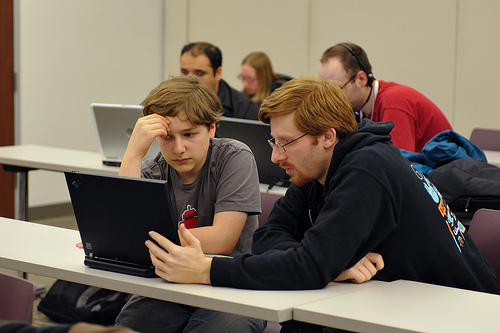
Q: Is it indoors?
A: Yes, it is indoors.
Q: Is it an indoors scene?
A: Yes, it is indoors.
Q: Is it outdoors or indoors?
A: It is indoors.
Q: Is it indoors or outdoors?
A: It is indoors.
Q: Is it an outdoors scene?
A: No, it is indoors.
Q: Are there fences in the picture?
A: No, there are no fences.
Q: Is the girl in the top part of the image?
A: Yes, the girl is in the top of the image.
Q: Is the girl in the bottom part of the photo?
A: No, the girl is in the top of the image.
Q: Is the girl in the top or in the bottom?
A: The girl is in the top of the image.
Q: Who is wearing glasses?
A: The girl is wearing glasses.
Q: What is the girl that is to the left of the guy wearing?
A: The girl is wearing glasses.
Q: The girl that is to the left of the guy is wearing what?
A: The girl is wearing glasses.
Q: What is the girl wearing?
A: The girl is wearing glasses.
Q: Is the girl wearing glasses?
A: Yes, the girl is wearing glasses.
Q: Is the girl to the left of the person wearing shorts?
A: No, the girl is wearing glasses.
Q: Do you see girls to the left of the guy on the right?
A: Yes, there is a girl to the left of the guy.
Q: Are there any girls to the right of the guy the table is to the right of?
A: No, the girl is to the left of the guy.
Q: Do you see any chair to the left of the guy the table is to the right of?
A: No, there is a girl to the left of the guy.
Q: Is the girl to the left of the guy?
A: Yes, the girl is to the left of the guy.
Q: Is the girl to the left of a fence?
A: No, the girl is to the left of the guy.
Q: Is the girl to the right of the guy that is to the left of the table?
A: No, the girl is to the left of the guy.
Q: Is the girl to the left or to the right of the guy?
A: The girl is to the left of the guy.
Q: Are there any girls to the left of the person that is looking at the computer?
A: Yes, there is a girl to the left of the person.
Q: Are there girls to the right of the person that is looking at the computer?
A: No, the girl is to the left of the person.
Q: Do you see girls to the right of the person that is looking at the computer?
A: No, the girl is to the left of the person.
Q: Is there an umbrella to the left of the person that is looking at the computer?
A: No, there is a girl to the left of the person.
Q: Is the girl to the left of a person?
A: Yes, the girl is to the left of a person.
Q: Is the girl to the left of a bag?
A: No, the girl is to the left of a person.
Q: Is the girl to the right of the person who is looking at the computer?
A: No, the girl is to the left of the person.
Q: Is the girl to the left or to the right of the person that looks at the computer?
A: The girl is to the left of the person.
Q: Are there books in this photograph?
A: No, there are no books.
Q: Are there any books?
A: No, there are no books.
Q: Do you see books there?
A: No, there are no books.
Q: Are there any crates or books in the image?
A: No, there are no books or crates.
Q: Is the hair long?
A: Yes, the hair is long.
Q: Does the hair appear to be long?
A: Yes, the hair is long.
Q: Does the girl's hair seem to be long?
A: Yes, the hair is long.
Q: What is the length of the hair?
A: The hair is long.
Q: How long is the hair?
A: The hair is long.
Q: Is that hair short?
A: No, the hair is long.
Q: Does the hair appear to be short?
A: No, the hair is long.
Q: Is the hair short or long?
A: The hair is long.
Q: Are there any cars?
A: No, there are no cars.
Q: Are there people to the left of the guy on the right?
A: Yes, there is a person to the left of the guy.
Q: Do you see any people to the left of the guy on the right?
A: Yes, there is a person to the left of the guy.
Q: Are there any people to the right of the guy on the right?
A: No, the person is to the left of the guy.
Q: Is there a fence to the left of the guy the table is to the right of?
A: No, there is a person to the left of the guy.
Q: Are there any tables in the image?
A: Yes, there is a table.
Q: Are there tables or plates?
A: Yes, there is a table.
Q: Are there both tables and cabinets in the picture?
A: No, there is a table but no cabinets.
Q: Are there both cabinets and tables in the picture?
A: No, there is a table but no cabinets.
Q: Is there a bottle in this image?
A: No, there are no bottles.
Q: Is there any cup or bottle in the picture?
A: No, there are no bottles or cups.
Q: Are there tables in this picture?
A: Yes, there is a table.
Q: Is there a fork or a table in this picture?
A: Yes, there is a table.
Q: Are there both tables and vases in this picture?
A: No, there is a table but no vases.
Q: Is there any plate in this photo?
A: No, there are no plates.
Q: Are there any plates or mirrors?
A: No, there are no plates or mirrors.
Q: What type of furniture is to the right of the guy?
A: The piece of furniture is a table.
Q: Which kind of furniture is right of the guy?
A: The piece of furniture is a table.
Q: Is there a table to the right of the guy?
A: Yes, there is a table to the right of the guy.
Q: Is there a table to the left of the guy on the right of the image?
A: No, the table is to the right of the guy.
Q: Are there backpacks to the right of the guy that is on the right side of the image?
A: No, there is a table to the right of the guy.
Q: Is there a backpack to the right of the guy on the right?
A: No, there is a table to the right of the guy.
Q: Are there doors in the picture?
A: Yes, there is a door.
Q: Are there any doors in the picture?
A: Yes, there is a door.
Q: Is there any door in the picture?
A: Yes, there is a door.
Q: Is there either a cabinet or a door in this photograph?
A: Yes, there is a door.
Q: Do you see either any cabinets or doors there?
A: Yes, there is a door.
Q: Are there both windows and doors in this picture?
A: No, there is a door but no windows.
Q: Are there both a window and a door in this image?
A: No, there is a door but no windows.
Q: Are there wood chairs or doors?
A: Yes, there is a wood door.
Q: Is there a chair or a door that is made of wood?
A: Yes, the door is made of wood.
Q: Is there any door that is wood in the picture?
A: Yes, there is a wood door.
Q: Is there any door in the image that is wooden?
A: Yes, there is a door that is wooden.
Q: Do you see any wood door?
A: Yes, there is a door that is made of wood.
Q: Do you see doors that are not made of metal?
A: Yes, there is a door that is made of wood.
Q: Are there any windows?
A: No, there are no windows.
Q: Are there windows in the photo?
A: No, there are no windows.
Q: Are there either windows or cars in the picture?
A: No, there are no windows or cars.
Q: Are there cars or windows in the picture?
A: No, there are no windows or cars.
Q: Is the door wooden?
A: Yes, the door is wooden.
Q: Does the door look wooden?
A: Yes, the door is wooden.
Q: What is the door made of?
A: The door is made of wood.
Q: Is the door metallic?
A: No, the door is wooden.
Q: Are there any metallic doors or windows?
A: No, there is a door but it is wooden.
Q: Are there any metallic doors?
A: No, there is a door but it is wooden.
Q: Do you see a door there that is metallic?
A: No, there is a door but it is wooden.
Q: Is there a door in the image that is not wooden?
A: No, there is a door but it is wooden.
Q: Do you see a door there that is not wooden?
A: No, there is a door but it is wooden.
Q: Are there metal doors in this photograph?
A: No, there is a door but it is made of wood.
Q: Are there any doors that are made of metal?
A: No, there is a door but it is made of wood.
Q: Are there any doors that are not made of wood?
A: No, there is a door but it is made of wood.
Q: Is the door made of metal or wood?
A: The door is made of wood.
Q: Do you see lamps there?
A: No, there are no lamps.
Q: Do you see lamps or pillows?
A: No, there are no lamps or pillows.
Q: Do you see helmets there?
A: No, there are no helmets.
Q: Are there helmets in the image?
A: No, there are no helmets.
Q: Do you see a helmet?
A: No, there are no helmets.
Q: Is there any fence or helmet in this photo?
A: No, there are no helmets or fences.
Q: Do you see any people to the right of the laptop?
A: Yes, there is a person to the right of the laptop.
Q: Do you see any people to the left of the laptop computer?
A: No, the person is to the right of the laptop computer.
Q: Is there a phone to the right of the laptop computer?
A: No, there is a person to the right of the laptop computer.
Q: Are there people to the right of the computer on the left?
A: Yes, there is a person to the right of the computer.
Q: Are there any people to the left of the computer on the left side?
A: No, the person is to the right of the computer.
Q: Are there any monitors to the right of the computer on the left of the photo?
A: No, there is a person to the right of the computer.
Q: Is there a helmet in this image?
A: No, there are no helmets.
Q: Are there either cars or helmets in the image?
A: No, there are no helmets or cars.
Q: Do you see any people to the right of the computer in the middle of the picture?
A: Yes, there is a person to the right of the computer.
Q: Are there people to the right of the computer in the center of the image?
A: Yes, there is a person to the right of the computer.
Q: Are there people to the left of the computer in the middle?
A: No, the person is to the right of the computer.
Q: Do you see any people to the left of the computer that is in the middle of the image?
A: No, the person is to the right of the computer.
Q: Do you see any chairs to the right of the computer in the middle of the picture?
A: No, there is a person to the right of the computer.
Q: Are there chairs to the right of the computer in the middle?
A: No, there is a person to the right of the computer.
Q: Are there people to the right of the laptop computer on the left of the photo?
A: Yes, there is a person to the right of the laptop.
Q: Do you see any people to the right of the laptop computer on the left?
A: Yes, there is a person to the right of the laptop.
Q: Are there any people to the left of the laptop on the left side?
A: No, the person is to the right of the laptop.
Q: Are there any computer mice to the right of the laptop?
A: No, there is a person to the right of the laptop.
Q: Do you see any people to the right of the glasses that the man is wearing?
A: Yes, there is a person to the right of the glasses.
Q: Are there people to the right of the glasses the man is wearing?
A: Yes, there is a person to the right of the glasses.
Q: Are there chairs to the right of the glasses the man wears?
A: No, there is a person to the right of the glasses.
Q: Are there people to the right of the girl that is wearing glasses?
A: Yes, there is a person to the right of the girl.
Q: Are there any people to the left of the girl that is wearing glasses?
A: No, the person is to the right of the girl.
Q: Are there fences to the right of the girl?
A: No, there is a person to the right of the girl.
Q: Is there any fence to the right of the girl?
A: No, there is a person to the right of the girl.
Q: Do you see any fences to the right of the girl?
A: No, there is a person to the right of the girl.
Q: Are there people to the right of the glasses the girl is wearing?
A: Yes, there is a person to the right of the glasses.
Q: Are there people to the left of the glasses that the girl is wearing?
A: No, the person is to the right of the glasses.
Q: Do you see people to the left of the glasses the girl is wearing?
A: No, the person is to the right of the glasses.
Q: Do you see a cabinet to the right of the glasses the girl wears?
A: No, there is a person to the right of the glasses.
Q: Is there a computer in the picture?
A: Yes, there is a computer.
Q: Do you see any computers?
A: Yes, there is a computer.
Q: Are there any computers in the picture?
A: Yes, there is a computer.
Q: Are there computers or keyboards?
A: Yes, there is a computer.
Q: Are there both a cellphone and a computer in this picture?
A: No, there is a computer but no cell phones.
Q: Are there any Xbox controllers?
A: No, there are no Xbox controllers.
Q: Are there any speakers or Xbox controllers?
A: No, there are no Xbox controllers or speakers.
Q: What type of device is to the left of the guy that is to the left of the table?
A: The device is a computer.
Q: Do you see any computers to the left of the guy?
A: Yes, there is a computer to the left of the guy.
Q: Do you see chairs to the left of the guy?
A: No, there is a computer to the left of the guy.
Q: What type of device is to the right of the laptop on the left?
A: The device is a computer.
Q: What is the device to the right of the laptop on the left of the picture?
A: The device is a computer.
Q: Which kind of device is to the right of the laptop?
A: The device is a computer.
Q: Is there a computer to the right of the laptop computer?
A: Yes, there is a computer to the right of the laptop computer.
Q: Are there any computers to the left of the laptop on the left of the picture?
A: No, the computer is to the right of the laptop.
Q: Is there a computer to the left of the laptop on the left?
A: No, the computer is to the right of the laptop.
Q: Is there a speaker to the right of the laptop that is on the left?
A: No, there is a computer to the right of the laptop.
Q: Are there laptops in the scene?
A: Yes, there is a laptop.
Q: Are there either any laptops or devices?
A: Yes, there is a laptop.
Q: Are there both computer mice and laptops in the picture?
A: No, there is a laptop but no computer mice.